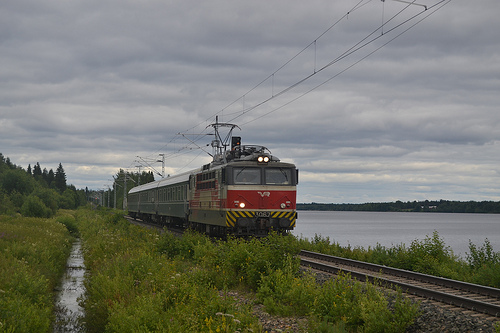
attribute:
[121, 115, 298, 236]
train — red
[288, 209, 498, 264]
water — body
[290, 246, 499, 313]
track — train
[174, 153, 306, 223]
train — red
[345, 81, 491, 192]
clouds — white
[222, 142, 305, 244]
train — yellow, black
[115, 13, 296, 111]
clouds — white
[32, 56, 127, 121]
clouds — white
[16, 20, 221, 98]
sky — blue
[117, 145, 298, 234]
train — red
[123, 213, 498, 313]
tracks — train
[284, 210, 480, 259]
river — small